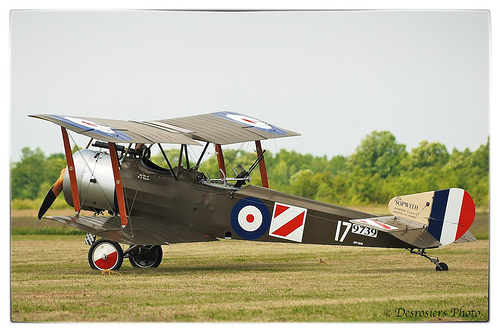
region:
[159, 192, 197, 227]
the plane is gray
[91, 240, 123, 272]
the wheel is red and white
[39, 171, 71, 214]
the perpeller is orange and black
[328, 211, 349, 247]
the number is white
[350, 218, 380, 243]
the number is black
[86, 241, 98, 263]
the tire is black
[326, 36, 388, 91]
the sky looks hazy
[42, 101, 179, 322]
the plane is on the ground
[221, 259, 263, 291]
the grass is green in color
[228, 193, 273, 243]
the target is blue white and red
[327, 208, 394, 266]
id number for plane is 17 9739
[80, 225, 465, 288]
there are 3 wheels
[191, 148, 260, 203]
area for a passenger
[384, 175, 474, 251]
red, white and blue colors painted on tail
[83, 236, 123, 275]
front wheel with red and white colors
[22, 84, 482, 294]
plane sitting empty on a field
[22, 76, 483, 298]
plane as it appears ready for flight.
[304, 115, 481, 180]
nice trees with foliage in the background.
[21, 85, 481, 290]
plane that is kept clean and painted.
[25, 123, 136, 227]
single engine plane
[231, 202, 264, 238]
red dot in a circle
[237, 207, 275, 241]
white ring around the red dot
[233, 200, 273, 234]
blue ring around the white ring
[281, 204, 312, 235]
red and white stripes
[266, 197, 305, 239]
stripes are in a box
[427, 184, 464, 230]
red, white and blue stripes on the tail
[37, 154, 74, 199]
propellar on the front of plane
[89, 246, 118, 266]
center of wheel is red and white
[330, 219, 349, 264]
17 written on side of plane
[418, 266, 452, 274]
wheel on the plane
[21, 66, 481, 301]
A vintage airplane is parked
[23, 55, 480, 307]
An old airplane is on display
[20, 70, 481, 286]
An airplane is parked in the grass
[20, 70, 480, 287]
A plane is parked in the clearing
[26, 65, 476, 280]
A World War I airplane has been restored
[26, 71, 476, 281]
World War I fighter from a museum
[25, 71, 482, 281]
A plane is ready to take off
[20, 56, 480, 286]
An old plane has just landed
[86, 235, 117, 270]
Wheel of an old airplane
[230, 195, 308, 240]
Markings on an old airplane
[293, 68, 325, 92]
part of a cloud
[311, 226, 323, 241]
part of a plane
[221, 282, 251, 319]
part of a ground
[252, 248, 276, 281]
part of a shade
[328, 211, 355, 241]
part of a number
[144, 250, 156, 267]
part of a wheel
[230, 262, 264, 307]
part of a ground